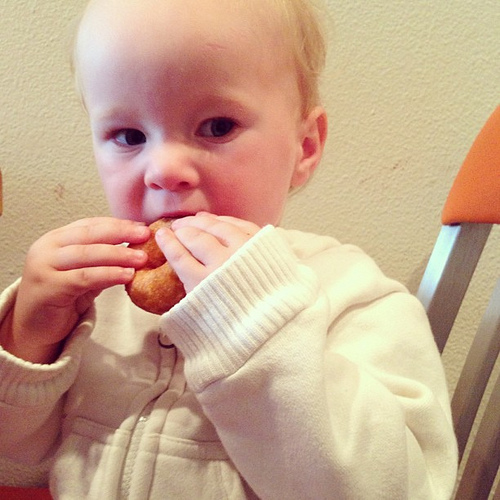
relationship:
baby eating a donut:
[2, 1, 457, 499] [122, 217, 187, 309]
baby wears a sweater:
[2, 1, 457, 499] [0, 226, 459, 499]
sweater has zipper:
[0, 226, 459, 499] [113, 328, 181, 499]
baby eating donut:
[2, 1, 457, 499] [122, 217, 187, 309]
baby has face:
[2, 1, 457, 499] [86, 83, 285, 239]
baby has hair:
[2, 1, 457, 499] [268, 1, 328, 117]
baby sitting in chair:
[2, 1, 457, 499] [413, 101, 499, 492]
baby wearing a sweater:
[2, 1, 457, 499] [0, 226, 459, 499]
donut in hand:
[122, 217, 187, 309] [154, 210, 262, 293]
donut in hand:
[122, 217, 187, 309] [24, 213, 150, 309]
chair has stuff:
[413, 101, 499, 492] [439, 102, 499, 225]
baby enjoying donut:
[2, 1, 457, 499] [122, 217, 187, 309]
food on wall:
[53, 184, 67, 196] [2, 3, 496, 500]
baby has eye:
[2, 1, 457, 499] [193, 117, 239, 138]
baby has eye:
[2, 1, 457, 499] [110, 127, 147, 146]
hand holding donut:
[154, 210, 262, 293] [122, 217, 187, 309]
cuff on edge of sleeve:
[161, 224, 318, 396] [154, 225, 457, 500]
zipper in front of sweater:
[113, 328, 181, 499] [0, 226, 459, 499]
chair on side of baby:
[413, 101, 499, 492] [2, 1, 457, 499]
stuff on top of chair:
[439, 102, 499, 225] [413, 101, 499, 492]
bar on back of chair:
[417, 223, 492, 352] [413, 101, 499, 492]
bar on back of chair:
[450, 276, 499, 464] [413, 101, 499, 492]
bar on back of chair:
[454, 371, 499, 498] [413, 101, 499, 492]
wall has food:
[2, 3, 496, 500] [53, 184, 67, 196]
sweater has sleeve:
[0, 226, 459, 499] [154, 225, 457, 500]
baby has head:
[2, 1, 457, 499] [72, 3, 331, 230]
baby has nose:
[2, 1, 457, 499] [144, 158, 200, 190]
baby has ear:
[2, 1, 457, 499] [293, 107, 328, 189]